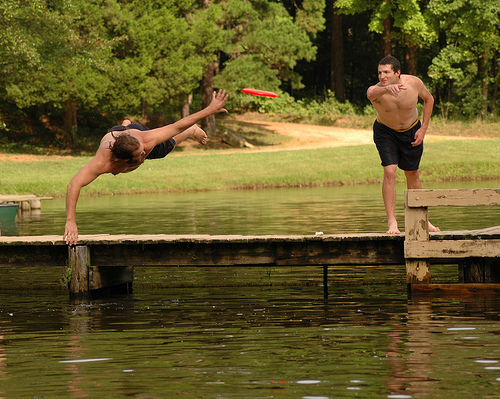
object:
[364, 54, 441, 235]
man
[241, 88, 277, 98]
frisbee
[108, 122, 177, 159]
black shorts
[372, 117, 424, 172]
black shorts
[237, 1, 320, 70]
leaves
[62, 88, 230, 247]
man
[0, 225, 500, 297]
dock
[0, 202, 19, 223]
boat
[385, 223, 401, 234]
foot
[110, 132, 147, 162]
head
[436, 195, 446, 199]
brown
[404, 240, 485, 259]
wooden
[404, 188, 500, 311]
fence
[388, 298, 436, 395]
reflection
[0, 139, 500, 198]
grass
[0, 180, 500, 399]
lake water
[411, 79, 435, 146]
hand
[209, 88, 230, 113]
hand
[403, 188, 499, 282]
paint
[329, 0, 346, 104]
tree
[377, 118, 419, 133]
waistband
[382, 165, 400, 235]
leg